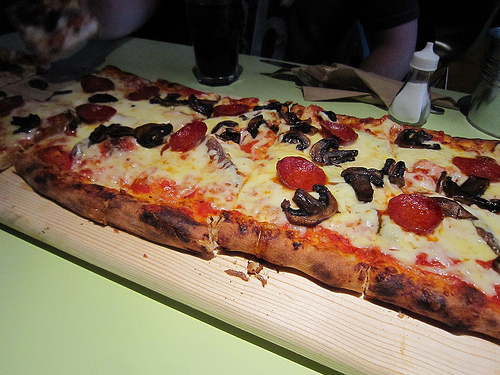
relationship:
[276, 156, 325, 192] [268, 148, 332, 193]
pepperoni of pepperoni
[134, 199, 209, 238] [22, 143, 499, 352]
area of crust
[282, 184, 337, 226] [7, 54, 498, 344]
mushroom on pizza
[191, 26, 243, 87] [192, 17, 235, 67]
cup with beverage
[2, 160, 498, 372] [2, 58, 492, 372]
piece of wood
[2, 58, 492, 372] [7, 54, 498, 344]
wood under pizza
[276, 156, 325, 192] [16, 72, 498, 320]
pepperoni as toppings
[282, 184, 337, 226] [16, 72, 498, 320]
mushroom as toppings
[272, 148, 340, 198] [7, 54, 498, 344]
pepperoni on pizza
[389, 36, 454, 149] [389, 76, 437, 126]
container of sugar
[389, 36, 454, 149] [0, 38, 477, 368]
container on table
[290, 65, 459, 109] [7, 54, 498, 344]
napkin behind pizza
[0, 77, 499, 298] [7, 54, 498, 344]
cheese on pizza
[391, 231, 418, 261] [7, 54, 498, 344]
cheese on pizza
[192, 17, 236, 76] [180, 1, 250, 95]
beverage in glass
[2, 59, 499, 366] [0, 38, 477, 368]
board on table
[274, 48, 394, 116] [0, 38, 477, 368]
napkin on table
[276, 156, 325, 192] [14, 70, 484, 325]
pepperoni on pizza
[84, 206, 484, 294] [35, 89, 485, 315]
crust on pizza.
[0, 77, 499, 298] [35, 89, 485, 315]
cheese on pizza.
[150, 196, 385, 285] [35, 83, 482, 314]
sauce on pizza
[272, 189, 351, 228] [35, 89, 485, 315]
mushroom on pizza.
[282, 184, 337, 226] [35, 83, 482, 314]
mushroom on pizza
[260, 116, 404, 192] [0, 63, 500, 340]
mushrooms on pizza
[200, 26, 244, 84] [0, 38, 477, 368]
cup on table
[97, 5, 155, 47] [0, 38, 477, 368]
elbow on table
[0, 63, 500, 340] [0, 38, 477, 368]
pizza on table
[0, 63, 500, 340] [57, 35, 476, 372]
pizza on table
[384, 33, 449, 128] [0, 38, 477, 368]
salt shaker on table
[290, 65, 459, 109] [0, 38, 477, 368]
napkin on table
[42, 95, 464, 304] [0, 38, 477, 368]
pizza on table